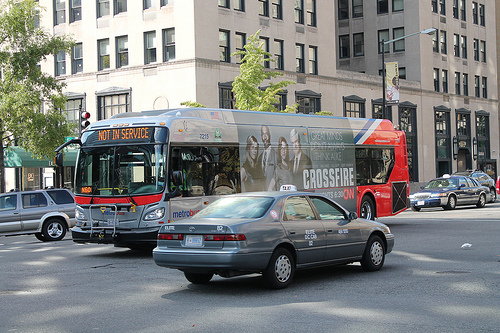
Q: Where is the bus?
A: On the street.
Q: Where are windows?
A: On buildings.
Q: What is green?
A: Trees.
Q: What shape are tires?
A: Round.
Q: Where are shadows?
A: On the ground.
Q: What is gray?
A: Car in front.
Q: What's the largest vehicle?
A: A bus.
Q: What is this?
A: A city street scene.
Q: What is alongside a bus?
A: A taxi.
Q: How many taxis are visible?
A: Two.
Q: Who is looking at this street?
A: The photographer.